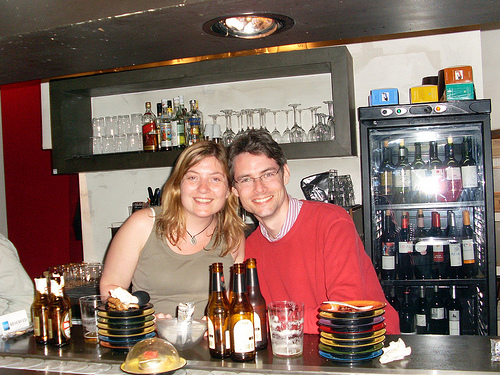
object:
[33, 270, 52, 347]
bottle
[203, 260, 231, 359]
bottle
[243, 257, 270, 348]
bottle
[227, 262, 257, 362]
bottle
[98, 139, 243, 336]
lady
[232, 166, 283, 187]
glasses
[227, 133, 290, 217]
man's face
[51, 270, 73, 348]
bottle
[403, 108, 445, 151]
wall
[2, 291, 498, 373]
bar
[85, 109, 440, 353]
people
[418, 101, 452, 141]
ground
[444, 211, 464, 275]
bottle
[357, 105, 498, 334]
cooler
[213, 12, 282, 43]
light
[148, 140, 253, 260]
hair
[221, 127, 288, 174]
hair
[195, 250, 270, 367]
bottle counter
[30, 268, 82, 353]
bottle counter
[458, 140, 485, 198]
bottles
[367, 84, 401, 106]
box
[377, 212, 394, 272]
bottle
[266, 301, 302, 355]
glass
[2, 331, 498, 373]
counter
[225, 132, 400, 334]
man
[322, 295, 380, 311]
spoon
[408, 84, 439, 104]
box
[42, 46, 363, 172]
shelf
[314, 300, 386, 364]
stack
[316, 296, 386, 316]
plate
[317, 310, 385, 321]
plate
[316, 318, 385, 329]
plate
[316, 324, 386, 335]
plate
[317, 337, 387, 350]
plate